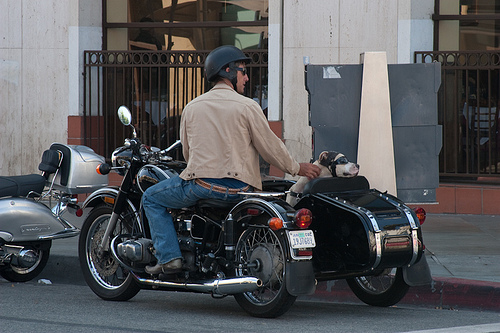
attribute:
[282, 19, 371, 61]
wall — white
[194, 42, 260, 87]
helmet — black, safety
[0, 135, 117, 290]
motorcycle — grey, silver, parked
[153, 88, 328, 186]
jacket — brown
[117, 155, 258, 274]
trouser — blue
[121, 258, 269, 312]
pipe — metallic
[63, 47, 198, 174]
gate — metal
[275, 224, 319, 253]
plate — license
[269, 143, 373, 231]
dog — sitting, wearing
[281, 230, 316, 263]
light — brake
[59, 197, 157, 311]
tire — motorcycle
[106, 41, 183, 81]
railing — black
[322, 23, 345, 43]
stone — gray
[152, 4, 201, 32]
window — large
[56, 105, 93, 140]
stripe — red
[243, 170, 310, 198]
straps — silver